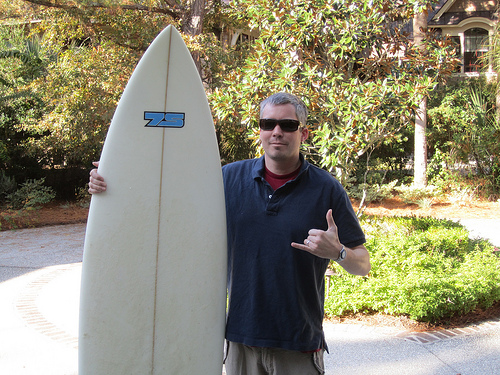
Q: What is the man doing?
A: Standing.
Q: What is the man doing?
A: Posing.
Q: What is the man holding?
A: Surfboard.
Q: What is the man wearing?
A: Shirt.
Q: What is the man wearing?
A: Pant.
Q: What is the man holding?
A: A surfboard.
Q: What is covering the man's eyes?
A: Sunglasses.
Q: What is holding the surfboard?
A: The man.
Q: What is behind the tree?
A: The house.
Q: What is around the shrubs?
A: The bricks.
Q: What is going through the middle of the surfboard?
A: The line.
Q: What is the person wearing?
A: The pants.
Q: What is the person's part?
A: The head.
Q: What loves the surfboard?
A: The man.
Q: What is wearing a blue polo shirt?
A: The man.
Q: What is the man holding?
A: A surfboard.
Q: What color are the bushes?
A: Green.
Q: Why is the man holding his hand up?
A: He is posing for a picture.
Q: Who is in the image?
A: A man.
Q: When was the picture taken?
A: During the day.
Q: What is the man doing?
A: Posing for a picture.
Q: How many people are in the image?
A: One.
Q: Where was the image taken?
A: In front of a house.